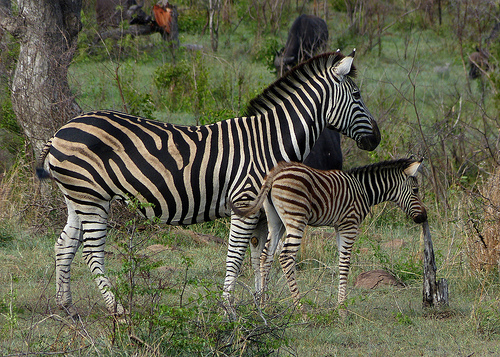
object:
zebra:
[227, 154, 428, 324]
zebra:
[35, 47, 381, 323]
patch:
[251, 236, 260, 248]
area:
[1, 0, 500, 356]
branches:
[0, 0, 500, 356]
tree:
[1, 0, 157, 236]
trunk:
[149, 1, 182, 46]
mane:
[352, 157, 416, 174]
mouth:
[413, 214, 428, 224]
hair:
[229, 200, 248, 217]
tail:
[225, 167, 278, 221]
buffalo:
[273, 15, 328, 78]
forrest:
[1, 0, 500, 356]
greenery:
[156, 60, 190, 86]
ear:
[334, 47, 357, 76]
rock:
[353, 268, 405, 291]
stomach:
[115, 195, 230, 225]